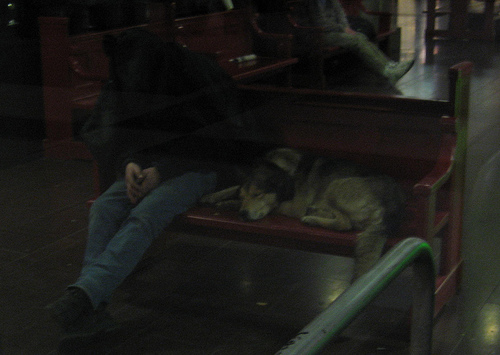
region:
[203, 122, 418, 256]
a brown husky type dog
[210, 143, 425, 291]
a brown dog sleeping on a bench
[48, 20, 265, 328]
a man with his head covered sitting on a bench.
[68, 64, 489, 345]
a red wooden bench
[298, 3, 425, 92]
a person with white shoes sitting on a bench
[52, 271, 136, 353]
black shoes on a man's feet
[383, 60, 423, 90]
white shoes on man's feet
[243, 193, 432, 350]
a metal rail with green paint on it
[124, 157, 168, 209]
a man's hands in a prayer position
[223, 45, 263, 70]
a paper sitting on a bench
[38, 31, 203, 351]
a man sleeping on bench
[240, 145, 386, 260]
a dog sleeping on a bench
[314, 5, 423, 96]
a person wearing white shoes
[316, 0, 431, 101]
a person wearing khaki pants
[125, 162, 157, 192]
hands resting in a lap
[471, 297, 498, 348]
light reflecting on a floor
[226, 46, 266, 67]
a magazine on the bench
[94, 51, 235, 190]
a person covered by a black jacket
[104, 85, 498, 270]
a hard wooden bench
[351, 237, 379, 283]
a fluffy brown tail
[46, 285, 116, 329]
Man wearing shoes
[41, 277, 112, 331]
Man wearing black shoes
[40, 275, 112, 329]
Man is wearing shoes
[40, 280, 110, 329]
Man is wearing black shoes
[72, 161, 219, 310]
Man wearing pants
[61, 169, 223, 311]
Man is wearing pants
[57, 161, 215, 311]
Man wearing blue pants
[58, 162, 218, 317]
Man is wearing blue pants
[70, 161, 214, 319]
Man wearing jeans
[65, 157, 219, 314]
Man is wearing blue jeans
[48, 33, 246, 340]
man in black jacket sitting on a bench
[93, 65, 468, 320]
red bench with a man and dog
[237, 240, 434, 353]
a silver railing by the bench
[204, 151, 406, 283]
dog sleeping on the bench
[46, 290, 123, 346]
the man's black tennis shoes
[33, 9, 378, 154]
longer red bench behind the man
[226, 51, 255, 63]
white piece of paper on other bench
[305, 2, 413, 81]
person sitting on far end of other bench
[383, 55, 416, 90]
white tennis shoes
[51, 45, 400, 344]
man sleeping beside his dog